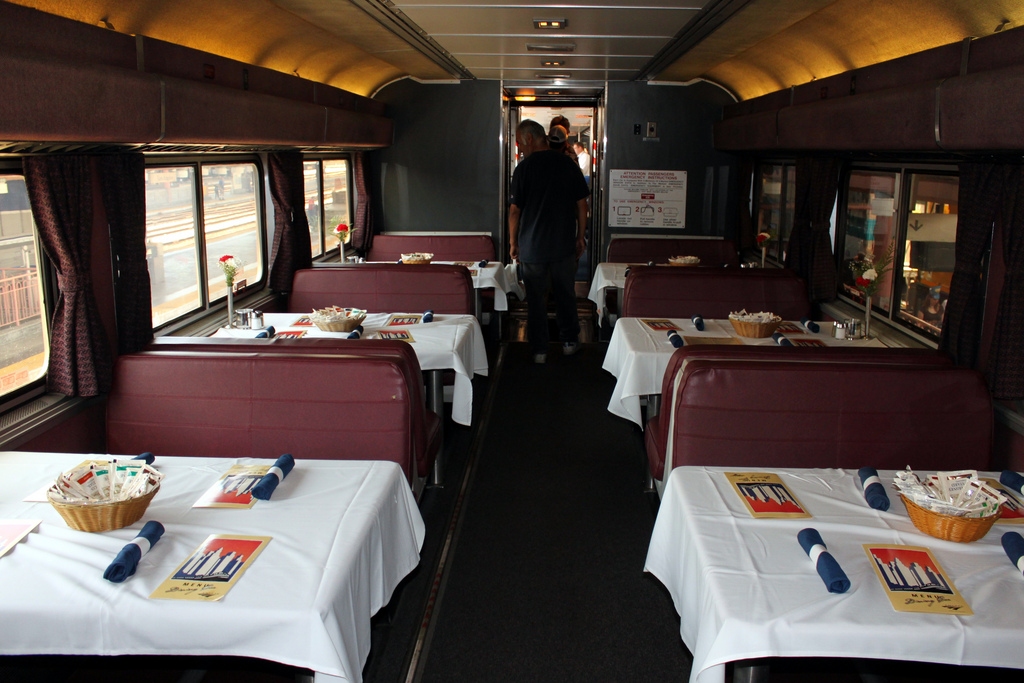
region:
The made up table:
[0, 436, 438, 675]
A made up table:
[631, 455, 1021, 672]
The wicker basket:
[45, 443, 166, 521]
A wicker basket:
[883, 461, 997, 538]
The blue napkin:
[102, 526, 166, 580]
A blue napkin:
[251, 450, 312, 499]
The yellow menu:
[151, 513, 270, 599]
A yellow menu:
[198, 452, 275, 509]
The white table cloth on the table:
[1, 435, 436, 645]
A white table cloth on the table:
[602, 436, 1014, 672]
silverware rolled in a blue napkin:
[779, 513, 859, 605]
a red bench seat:
[109, 345, 433, 466]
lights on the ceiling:
[516, 10, 571, 116]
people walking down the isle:
[498, 100, 596, 373]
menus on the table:
[710, 450, 800, 545]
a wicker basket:
[883, 450, 1004, 561]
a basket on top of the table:
[24, 444, 195, 536]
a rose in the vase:
[188, 242, 250, 347]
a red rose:
[206, 237, 248, 277]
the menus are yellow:
[181, 531, 292, 623]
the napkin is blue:
[103, 519, 179, 578]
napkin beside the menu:
[204, 452, 313, 528]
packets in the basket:
[51, 452, 162, 516]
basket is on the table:
[54, 463, 166, 531]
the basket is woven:
[54, 501, 153, 539]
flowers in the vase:
[215, 248, 244, 324]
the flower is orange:
[222, 248, 238, 272]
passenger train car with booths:
[6, 2, 1021, 677]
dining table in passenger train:
[640, 461, 1023, 680]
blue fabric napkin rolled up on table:
[796, 524, 851, 592]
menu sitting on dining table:
[145, 527, 276, 605]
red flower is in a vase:
[217, 250, 244, 331]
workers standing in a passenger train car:
[506, 114, 595, 367]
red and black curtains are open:
[21, 149, 119, 400]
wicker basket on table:
[46, 455, 165, 533]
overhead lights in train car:
[629, 2, 1021, 105]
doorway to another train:
[498, 78, 609, 297]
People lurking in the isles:
[498, 103, 639, 383]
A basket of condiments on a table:
[39, 454, 161, 530]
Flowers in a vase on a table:
[212, 249, 235, 322]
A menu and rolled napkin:
[200, 448, 298, 502]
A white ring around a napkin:
[797, 540, 832, 563]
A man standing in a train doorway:
[509, 107, 589, 360]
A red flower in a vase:
[334, 220, 353, 258]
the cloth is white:
[280, 544, 347, 611]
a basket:
[63, 465, 155, 522]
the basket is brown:
[54, 446, 159, 524]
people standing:
[517, 116, 591, 254]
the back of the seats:
[126, 351, 395, 465]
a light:
[814, 23, 890, 61]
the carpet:
[503, 570, 574, 634]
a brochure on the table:
[863, 532, 953, 618]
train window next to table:
[0, 173, 53, 397]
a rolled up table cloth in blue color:
[101, 514, 163, 594]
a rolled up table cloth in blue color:
[253, 446, 295, 507]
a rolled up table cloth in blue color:
[793, 516, 857, 596]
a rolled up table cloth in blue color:
[849, 459, 897, 514]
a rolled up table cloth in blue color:
[995, 522, 1022, 581]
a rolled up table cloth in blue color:
[335, 320, 368, 343]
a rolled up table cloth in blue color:
[249, 322, 279, 345]